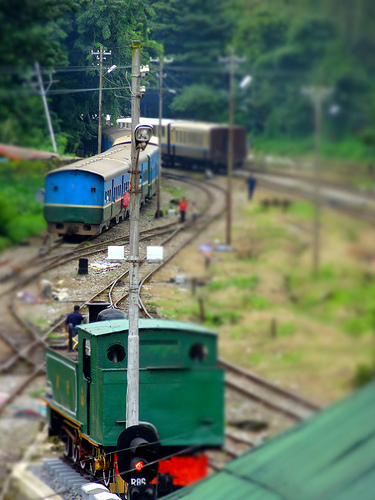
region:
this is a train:
[51, 154, 127, 227]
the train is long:
[58, 158, 115, 225]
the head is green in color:
[164, 345, 210, 393]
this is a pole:
[113, 182, 153, 238]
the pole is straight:
[124, 176, 151, 240]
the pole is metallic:
[117, 167, 152, 242]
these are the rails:
[23, 257, 63, 285]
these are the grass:
[302, 276, 346, 308]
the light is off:
[131, 121, 154, 146]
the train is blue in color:
[61, 178, 91, 204]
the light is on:
[80, 431, 164, 483]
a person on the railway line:
[51, 294, 87, 341]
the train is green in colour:
[51, 316, 226, 453]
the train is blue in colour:
[33, 139, 142, 237]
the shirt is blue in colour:
[61, 307, 72, 325]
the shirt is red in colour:
[174, 201, 186, 206]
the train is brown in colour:
[174, 113, 223, 154]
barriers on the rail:
[97, 239, 185, 266]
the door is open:
[72, 334, 104, 437]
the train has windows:
[103, 180, 128, 200]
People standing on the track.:
[173, 179, 267, 220]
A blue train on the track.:
[50, 143, 136, 225]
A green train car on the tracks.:
[42, 320, 220, 434]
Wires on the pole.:
[45, 57, 369, 94]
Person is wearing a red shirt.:
[174, 195, 192, 240]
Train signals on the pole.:
[117, 413, 166, 486]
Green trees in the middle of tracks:
[250, 256, 349, 322]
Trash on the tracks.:
[25, 272, 79, 308]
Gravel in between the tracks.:
[51, 266, 110, 302]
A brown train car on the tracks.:
[157, 110, 245, 172]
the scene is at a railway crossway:
[24, 29, 351, 362]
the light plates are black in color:
[130, 424, 163, 489]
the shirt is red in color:
[180, 198, 190, 208]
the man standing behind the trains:
[164, 173, 190, 242]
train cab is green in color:
[49, 320, 209, 426]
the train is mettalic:
[50, 172, 121, 226]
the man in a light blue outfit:
[242, 166, 262, 209]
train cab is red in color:
[170, 456, 198, 479]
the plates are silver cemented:
[26, 459, 95, 493]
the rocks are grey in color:
[91, 270, 137, 296]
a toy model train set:
[12, 41, 298, 480]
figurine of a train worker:
[170, 187, 205, 235]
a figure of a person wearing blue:
[54, 291, 95, 354]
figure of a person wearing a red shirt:
[172, 182, 193, 227]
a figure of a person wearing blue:
[240, 158, 266, 210]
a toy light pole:
[111, 96, 179, 471]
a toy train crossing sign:
[101, 418, 188, 494]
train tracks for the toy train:
[38, 232, 204, 302]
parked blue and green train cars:
[28, 107, 189, 272]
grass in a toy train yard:
[187, 182, 369, 368]